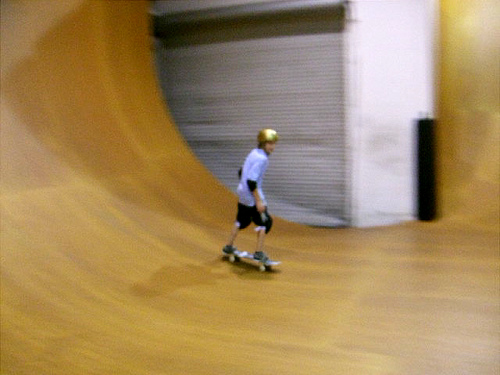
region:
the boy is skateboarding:
[206, 95, 341, 321]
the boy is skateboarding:
[214, 110, 296, 281]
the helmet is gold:
[253, 115, 293, 160]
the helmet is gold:
[238, 105, 307, 162]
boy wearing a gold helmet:
[228, 107, 280, 152]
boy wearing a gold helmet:
[199, 85, 314, 332]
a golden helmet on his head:
[255, 128, 284, 149]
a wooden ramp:
[41, 66, 183, 211]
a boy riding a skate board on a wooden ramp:
[224, 128, 296, 273]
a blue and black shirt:
[232, 148, 282, 211]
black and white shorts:
[228, 198, 278, 239]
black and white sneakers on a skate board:
[217, 240, 283, 265]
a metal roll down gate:
[153, 7, 361, 221]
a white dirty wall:
[339, 6, 434, 223]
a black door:
[413, 115, 445, 228]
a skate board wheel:
[220, 252, 244, 267]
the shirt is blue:
[232, 149, 280, 201]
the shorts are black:
[229, 196, 286, 227]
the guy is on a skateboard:
[207, 125, 319, 295]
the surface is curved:
[66, 16, 218, 312]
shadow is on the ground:
[125, 252, 206, 299]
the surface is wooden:
[97, 221, 192, 318]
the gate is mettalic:
[221, 51, 335, 141]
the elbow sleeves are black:
[241, 174, 265, 194]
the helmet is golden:
[249, 127, 296, 147]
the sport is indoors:
[224, 131, 345, 292]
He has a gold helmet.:
[250, 119, 283, 145]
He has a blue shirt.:
[220, 150, 277, 212]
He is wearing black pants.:
[227, 205, 280, 225]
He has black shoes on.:
[216, 240, 281, 272]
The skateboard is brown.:
[223, 251, 279, 278]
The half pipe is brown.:
[2, 2, 496, 361]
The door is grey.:
[156, 14, 363, 227]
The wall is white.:
[346, 6, 426, 225]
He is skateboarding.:
[211, 120, 306, 290]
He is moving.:
[207, 120, 308, 291]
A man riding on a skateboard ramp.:
[177, 115, 299, 287]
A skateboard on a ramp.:
[214, 220, 303, 276]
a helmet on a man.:
[250, 118, 280, 159]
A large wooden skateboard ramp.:
[1, 3, 498, 369]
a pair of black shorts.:
[224, 196, 275, 242]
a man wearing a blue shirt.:
[229, 148, 281, 207]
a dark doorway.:
[407, 109, 444, 233]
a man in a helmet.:
[244, 110, 288, 145]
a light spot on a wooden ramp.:
[281, 240, 381, 369]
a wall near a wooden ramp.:
[156, 23, 353, 213]